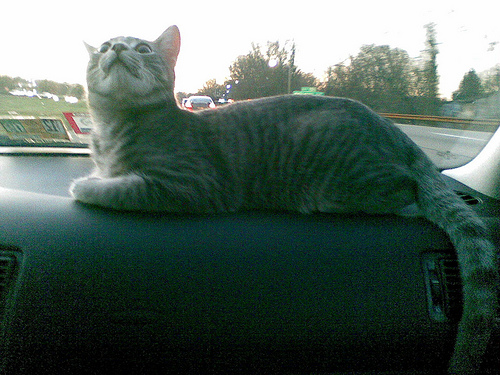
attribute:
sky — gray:
[193, 0, 420, 35]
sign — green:
[301, 82, 321, 96]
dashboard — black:
[79, 204, 391, 347]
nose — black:
[113, 40, 125, 55]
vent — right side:
[417, 248, 463, 330]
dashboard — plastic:
[66, 213, 427, 360]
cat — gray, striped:
[67, 23, 498, 373]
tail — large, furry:
[428, 175, 499, 369]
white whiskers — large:
[125, 49, 170, 99]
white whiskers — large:
[87, 44, 112, 86]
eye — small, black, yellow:
[134, 42, 154, 58]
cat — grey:
[61, 35, 498, 240]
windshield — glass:
[1, 7, 496, 180]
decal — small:
[1, 113, 74, 148]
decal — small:
[58, 104, 92, 137]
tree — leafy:
[413, 26, 440, 106]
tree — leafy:
[319, 40, 415, 92]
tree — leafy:
[199, 35, 310, 99]